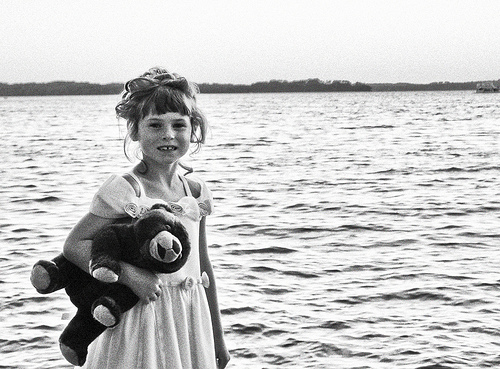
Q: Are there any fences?
A: No, there are no fences.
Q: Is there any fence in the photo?
A: No, there are no fences.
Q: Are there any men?
A: No, there are no men.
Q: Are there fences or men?
A: No, there are no men or fences.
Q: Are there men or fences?
A: No, there are no men or fences.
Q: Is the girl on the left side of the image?
A: Yes, the girl is on the left of the image.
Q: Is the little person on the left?
A: Yes, the girl is on the left of the image.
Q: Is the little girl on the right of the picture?
A: No, the girl is on the left of the image.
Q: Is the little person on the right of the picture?
A: No, the girl is on the left of the image.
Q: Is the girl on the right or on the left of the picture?
A: The girl is on the left of the image.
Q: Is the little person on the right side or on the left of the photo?
A: The girl is on the left of the image.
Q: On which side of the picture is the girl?
A: The girl is on the left of the image.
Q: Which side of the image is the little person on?
A: The girl is on the left of the image.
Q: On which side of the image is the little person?
A: The girl is on the left of the image.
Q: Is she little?
A: Yes, the girl is little.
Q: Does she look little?
A: Yes, the girl is little.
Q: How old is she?
A: The girl is little.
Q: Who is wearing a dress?
A: The girl is wearing a dress.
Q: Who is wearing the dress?
A: The girl is wearing a dress.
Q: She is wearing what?
A: The girl is wearing a dress.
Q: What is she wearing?
A: The girl is wearing a dress.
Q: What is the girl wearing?
A: The girl is wearing a dress.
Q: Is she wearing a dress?
A: Yes, the girl is wearing a dress.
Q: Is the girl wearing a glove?
A: No, the girl is wearing a dress.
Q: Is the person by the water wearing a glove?
A: No, the girl is wearing a dress.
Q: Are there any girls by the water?
A: Yes, there is a girl by the water.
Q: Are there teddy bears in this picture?
A: Yes, there is a teddy bear.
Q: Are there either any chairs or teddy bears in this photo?
A: Yes, there is a teddy bear.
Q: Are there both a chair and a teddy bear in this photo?
A: No, there is a teddy bear but no chairs.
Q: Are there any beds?
A: No, there are no beds.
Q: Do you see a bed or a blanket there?
A: No, there are no beds or blankets.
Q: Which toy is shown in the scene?
A: The toy is a teddy bear.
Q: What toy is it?
A: The toy is a teddy bear.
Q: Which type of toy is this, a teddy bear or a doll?
A: This is a teddy bear.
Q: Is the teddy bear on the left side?
A: Yes, the teddy bear is on the left of the image.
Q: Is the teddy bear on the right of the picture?
A: No, the teddy bear is on the left of the image.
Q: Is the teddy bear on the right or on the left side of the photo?
A: The teddy bear is on the left of the image.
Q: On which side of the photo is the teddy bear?
A: The teddy bear is on the left of the image.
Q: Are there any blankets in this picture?
A: No, there are no blankets.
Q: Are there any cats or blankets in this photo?
A: No, there are no blankets or cats.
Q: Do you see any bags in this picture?
A: No, there are no bags.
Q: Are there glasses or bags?
A: No, there are no bags or glasses.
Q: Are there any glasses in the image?
A: No, there are no glasses.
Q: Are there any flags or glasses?
A: No, there are no glasses or flags.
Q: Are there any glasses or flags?
A: No, there are no glasses or flags.